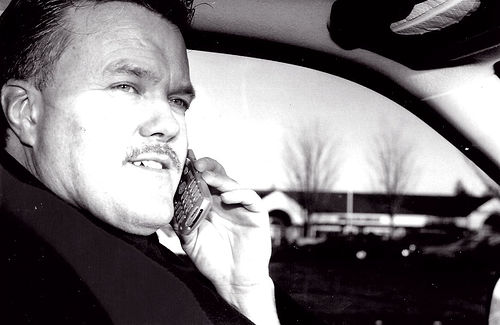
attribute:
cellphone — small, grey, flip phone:
[171, 148, 213, 238]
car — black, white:
[0, 0, 499, 324]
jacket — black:
[0, 148, 257, 324]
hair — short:
[0, 1, 195, 84]